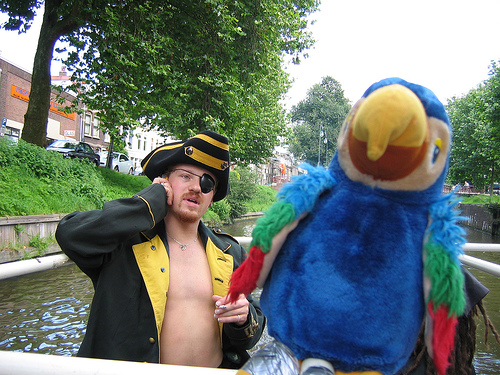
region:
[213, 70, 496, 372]
large stuffed animal parrot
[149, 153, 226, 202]
man is wearing an eye patch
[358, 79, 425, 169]
parrots beak is yellow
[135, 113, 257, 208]
pirate hat is yellow and black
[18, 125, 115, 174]
car next to tree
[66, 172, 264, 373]
pirate jacket is yellow and black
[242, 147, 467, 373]
parrot wings are blue, green and red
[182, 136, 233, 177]
two buttons on the pirate hat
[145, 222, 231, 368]
man is not wearing a shirt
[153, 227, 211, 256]
silver necklace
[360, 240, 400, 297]
aprt of a ball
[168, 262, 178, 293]
part of a chest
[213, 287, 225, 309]
part of a hanmd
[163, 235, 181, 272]
part of a necklace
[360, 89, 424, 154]
YELLOW NOSE ON THE BIRD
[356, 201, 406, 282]
BLUE ON THE BIRD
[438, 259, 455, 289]
GREEN ON THE ARM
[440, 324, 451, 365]
RED ON THE HAND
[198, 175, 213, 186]
PATCH ON THE EYE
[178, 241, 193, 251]
NECKLACE ON THE CHEST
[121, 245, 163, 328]
MAN COAT WIDE OPEN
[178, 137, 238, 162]
MAN WEARING A HAT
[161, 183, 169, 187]
RING ON THE FINGURE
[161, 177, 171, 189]
PHONE ON THE EAR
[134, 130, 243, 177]
Black and yellow pirate hat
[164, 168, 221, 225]
Man is wearing black eye patch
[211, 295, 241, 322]
Man is holding a cigarette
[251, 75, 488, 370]
Large blue stuffed bird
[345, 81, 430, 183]
Yellow and brown beak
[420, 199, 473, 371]
Blue, green and red wings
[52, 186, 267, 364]
Unbuttoned black and yellow jacket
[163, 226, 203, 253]
Silver emblem on chain on man's neck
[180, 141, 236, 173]
Two black buttons on hat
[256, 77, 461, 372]
stuffed blue parrot toy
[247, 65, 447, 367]
stuffed blue parrot toy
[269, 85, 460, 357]
stuffed blue parrot toy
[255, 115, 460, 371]
stuffed blue parrot toy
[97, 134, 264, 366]
man dressed up as pirate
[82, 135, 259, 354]
man dressed up as pirate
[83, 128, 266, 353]
man dressed up as pirate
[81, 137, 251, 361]
man dressed up as pirate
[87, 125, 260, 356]
man dressed up as pirate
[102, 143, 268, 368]
man dressed up as pirate